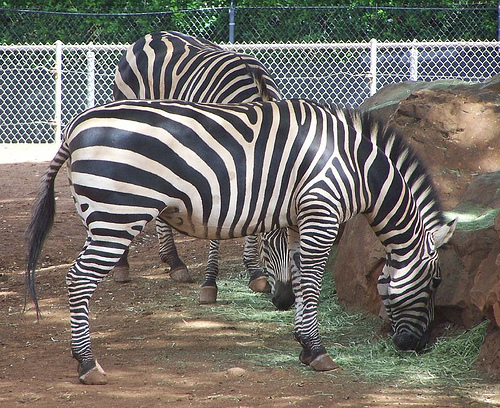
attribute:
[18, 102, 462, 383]
stripes — black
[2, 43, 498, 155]
gray fence — gray 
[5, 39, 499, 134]
fence — white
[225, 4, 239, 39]
fencepost — metal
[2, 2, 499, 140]
fence — chainlink, black, white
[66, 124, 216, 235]
stripe — black, Thick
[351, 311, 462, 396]
grass — green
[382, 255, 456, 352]
face — long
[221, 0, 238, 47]
pole — blue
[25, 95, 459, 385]
zebra — pictured, black, white, very dark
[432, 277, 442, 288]
eye — black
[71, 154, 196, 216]
stripe — black, thick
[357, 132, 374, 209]
stripe — black, thick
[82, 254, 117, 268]
stripe — thick, black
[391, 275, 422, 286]
stripe — black, thick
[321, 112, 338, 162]
stripe — black, thick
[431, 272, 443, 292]
eye — black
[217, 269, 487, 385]
grass — green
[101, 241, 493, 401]
hay — green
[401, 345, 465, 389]
grass — green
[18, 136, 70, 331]
tail — long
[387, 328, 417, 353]
mouth — black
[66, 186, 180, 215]
stripe — black, Thick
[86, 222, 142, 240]
stripe — Thick, black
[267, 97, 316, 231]
stripe — Thick, black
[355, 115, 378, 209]
stripe — black, thick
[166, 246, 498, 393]
grass — green